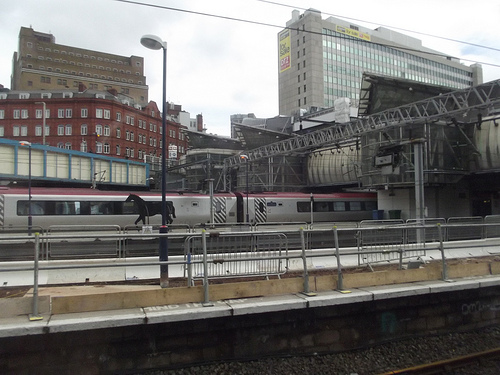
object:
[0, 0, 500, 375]
city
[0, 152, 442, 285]
street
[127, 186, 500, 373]
road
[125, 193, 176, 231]
horse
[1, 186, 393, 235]
train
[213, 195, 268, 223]
gate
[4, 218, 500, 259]
tracks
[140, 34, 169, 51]
light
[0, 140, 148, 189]
building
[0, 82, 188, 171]
building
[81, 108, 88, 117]
window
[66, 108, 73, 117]
window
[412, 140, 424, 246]
pipe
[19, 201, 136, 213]
window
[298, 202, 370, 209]
window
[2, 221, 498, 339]
fence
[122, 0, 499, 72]
wire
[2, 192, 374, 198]
top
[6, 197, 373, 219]
side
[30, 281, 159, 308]
platform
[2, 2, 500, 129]
sky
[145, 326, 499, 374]
gravel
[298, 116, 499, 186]
walkway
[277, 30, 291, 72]
advertisement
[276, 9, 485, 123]
building